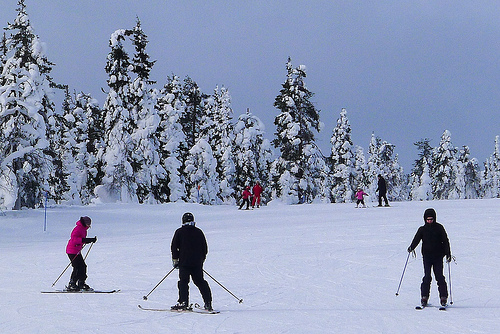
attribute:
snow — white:
[3, 172, 495, 331]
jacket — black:
[169, 222, 207, 265]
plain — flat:
[1, 197, 498, 332]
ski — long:
[129, 297, 178, 319]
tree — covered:
[97, 8, 164, 221]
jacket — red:
[251, 185, 264, 197]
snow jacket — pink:
[62, 221, 89, 259]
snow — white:
[35, 212, 430, 318]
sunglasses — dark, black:
[418, 215, 436, 222]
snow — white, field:
[6, 206, 493, 324]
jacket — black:
[409, 222, 451, 260]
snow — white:
[0, 199, 498, 332]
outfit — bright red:
[250, 183, 258, 204]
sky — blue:
[2, 1, 499, 164]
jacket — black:
[409, 209, 451, 262]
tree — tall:
[229, 105, 264, 209]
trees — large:
[0, 0, 499, 203]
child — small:
[353, 182, 366, 209]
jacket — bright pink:
[351, 187, 368, 199]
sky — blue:
[43, 3, 495, 198]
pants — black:
[59, 246, 91, 289]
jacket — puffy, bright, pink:
[54, 209, 93, 251]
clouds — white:
[157, 16, 224, 57]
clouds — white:
[163, 24, 239, 62]